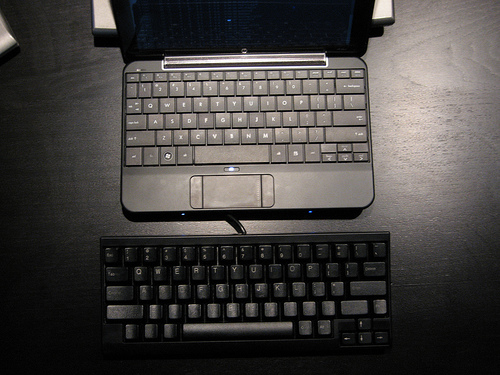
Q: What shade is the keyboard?
A: Gray.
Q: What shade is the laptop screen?
A: Black.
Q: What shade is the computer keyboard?
A: Black.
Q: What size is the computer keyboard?
A: It is full size.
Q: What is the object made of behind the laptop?
A: Metal.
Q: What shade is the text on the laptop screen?
A: Blue.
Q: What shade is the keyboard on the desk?
A: Black.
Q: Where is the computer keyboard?
A: In front of the laptop.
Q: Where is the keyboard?
A: On a table.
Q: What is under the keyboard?
A: A table.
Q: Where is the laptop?
A: On a table.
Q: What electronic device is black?
A: The laptop.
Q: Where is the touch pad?
A: On the laptop.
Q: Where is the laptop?
A: Behind the keyboard.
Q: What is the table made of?
A: Wood.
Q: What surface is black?
A: The table.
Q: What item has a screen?
A: The laptop.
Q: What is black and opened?
A: Laptop.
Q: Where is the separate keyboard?
A: In front of lap top.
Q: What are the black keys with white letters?
A: Buttons on keyboard.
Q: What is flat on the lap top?
A: Screen.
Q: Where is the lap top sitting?
A: On table.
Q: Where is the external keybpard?
A: In front of the lap top.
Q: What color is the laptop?
A: Black.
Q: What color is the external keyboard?
A: Black.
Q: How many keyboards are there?
A: Two.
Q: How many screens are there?
A: One.